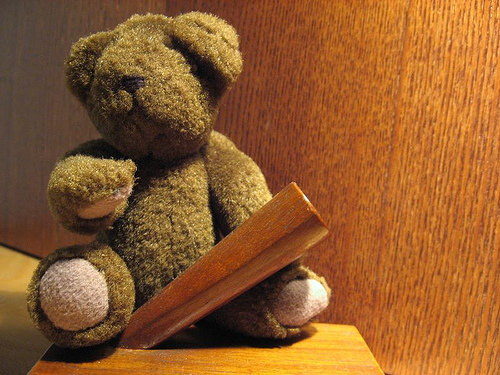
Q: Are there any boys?
A: No, there are no boys.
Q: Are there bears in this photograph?
A: Yes, there is a bear.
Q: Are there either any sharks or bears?
A: Yes, there is a bear.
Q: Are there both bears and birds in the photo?
A: No, there is a bear but no birds.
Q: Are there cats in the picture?
A: No, there are no cats.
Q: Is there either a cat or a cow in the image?
A: No, there are no cats or cows.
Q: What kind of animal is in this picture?
A: The animal is a bear.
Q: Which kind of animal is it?
A: The animal is a bear.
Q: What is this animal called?
A: This is a bear.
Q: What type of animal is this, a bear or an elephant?
A: This is a bear.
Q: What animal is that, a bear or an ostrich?
A: That is a bear.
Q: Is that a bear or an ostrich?
A: That is a bear.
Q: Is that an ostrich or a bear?
A: That is a bear.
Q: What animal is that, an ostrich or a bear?
A: That is a bear.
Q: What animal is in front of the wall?
A: The bear is in front of the wall.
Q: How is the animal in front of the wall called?
A: The animal is a bear.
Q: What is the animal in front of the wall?
A: The animal is a bear.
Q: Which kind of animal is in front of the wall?
A: The animal is a bear.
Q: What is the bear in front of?
A: The bear is in front of the wall.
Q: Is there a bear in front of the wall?
A: Yes, there is a bear in front of the wall.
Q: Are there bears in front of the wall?
A: Yes, there is a bear in front of the wall.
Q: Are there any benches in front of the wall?
A: No, there is a bear in front of the wall.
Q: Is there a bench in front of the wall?
A: No, there is a bear in front of the wall.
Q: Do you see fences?
A: No, there are no fences.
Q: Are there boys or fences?
A: No, there are no fences or boys.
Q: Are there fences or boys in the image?
A: No, there are no fences or boys.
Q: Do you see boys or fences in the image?
A: No, there are no fences or boys.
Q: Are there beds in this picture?
A: No, there are no beds.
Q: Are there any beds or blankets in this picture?
A: No, there are no beds or blankets.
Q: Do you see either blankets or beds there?
A: No, there are no beds or blankets.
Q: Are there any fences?
A: No, there are no fences.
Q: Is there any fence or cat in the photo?
A: No, there are no fences or cats.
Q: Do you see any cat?
A: No, there are no cats.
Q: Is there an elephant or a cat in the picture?
A: No, there are no cats or elephants.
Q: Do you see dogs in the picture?
A: No, there are no dogs.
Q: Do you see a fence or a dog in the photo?
A: No, there are no dogs or fences.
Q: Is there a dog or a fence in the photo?
A: No, there are no dogs or fences.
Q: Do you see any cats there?
A: No, there are no cats.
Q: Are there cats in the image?
A: No, there are no cats.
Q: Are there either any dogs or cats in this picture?
A: No, there are no cats or dogs.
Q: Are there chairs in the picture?
A: No, there are no chairs.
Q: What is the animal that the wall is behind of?
A: The animal is a bear.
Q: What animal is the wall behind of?
A: The wall is behind the bear.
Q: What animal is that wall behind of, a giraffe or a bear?
A: The wall is behind a bear.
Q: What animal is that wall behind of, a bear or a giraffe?
A: The wall is behind a bear.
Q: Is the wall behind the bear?
A: Yes, the wall is behind the bear.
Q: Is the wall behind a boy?
A: No, the wall is behind the bear.